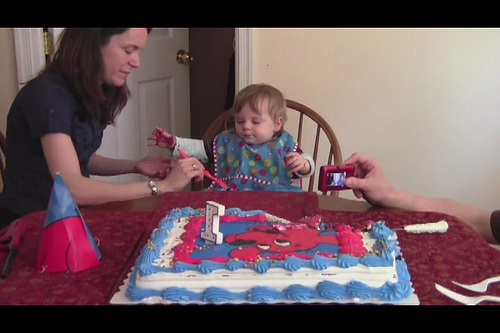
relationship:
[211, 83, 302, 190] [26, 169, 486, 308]
child at birthday party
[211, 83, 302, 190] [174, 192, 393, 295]
child eating cake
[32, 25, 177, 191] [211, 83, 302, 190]
woman feeding child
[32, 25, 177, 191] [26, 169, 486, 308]
woman at birthday party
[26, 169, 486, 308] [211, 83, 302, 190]
birthday party with child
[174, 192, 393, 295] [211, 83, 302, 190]
cake near child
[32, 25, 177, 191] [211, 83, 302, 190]
woman near child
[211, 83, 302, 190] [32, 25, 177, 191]
child near woman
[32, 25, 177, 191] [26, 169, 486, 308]
woman enjoying birthday party